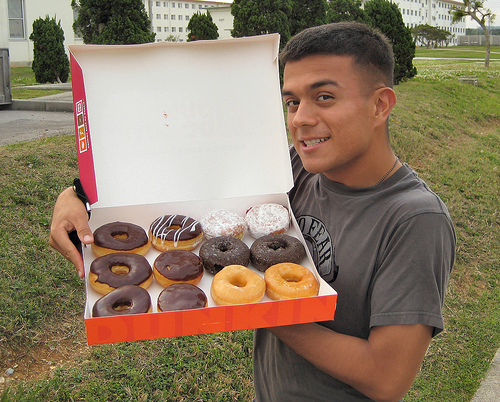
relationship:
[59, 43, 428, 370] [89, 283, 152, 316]
boy holding donut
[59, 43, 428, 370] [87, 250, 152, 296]
boy holding donut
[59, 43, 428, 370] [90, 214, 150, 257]
boy holding donut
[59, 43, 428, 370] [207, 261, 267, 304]
boy holding donut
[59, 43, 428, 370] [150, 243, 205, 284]
boy holding donut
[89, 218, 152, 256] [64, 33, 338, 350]
donut sitting in box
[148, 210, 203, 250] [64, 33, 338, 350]
donut sitting in box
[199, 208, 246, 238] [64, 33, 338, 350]
donut sitting in box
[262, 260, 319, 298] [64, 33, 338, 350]
donut sitting in box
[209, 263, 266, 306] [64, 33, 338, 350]
donut sitting in box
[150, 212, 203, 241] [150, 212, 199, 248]
frosting covering frosting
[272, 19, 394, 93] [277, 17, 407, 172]
hair belonging to man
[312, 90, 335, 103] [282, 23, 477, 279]
eye belonging to man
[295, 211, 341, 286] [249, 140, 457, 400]
logo printed on shirt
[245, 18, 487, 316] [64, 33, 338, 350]
he holding box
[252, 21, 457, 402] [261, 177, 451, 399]
he wearing shirt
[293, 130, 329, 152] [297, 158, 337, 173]
mouth and chin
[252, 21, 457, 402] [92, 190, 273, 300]
he with donuts